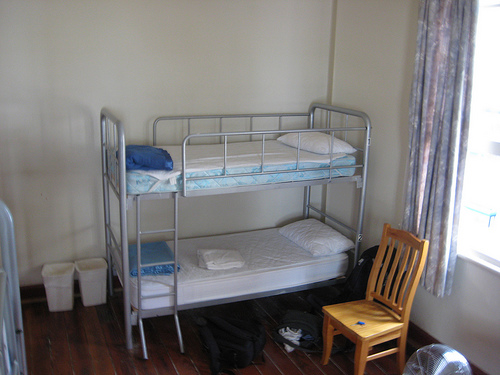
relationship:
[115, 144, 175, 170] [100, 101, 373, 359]
blanket laying on bed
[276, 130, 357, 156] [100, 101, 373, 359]
pillow laying on bed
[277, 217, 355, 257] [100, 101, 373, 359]
pillow laying on bed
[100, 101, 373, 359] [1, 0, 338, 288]
bed against wall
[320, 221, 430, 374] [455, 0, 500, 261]
chair sitting near window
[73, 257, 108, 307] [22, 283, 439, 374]
waste basket sitting on floor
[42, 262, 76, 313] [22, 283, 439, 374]
waste basket sitting on floor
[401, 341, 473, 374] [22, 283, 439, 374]
fan sitting on floor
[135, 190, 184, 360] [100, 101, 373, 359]
ladder on bed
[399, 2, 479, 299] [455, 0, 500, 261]
curtain on window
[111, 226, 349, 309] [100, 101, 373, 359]
mattress on bed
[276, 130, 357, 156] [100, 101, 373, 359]
pillow on bed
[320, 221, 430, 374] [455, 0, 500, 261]
chair in front of window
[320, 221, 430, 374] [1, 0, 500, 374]
chair in room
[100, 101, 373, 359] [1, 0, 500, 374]
bed in room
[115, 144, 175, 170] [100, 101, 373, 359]
blanket on bed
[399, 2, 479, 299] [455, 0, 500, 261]
curtain for window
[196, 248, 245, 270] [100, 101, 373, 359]
sheet for bed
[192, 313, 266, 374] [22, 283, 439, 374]
back pack on floor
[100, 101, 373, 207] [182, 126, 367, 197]
top has guard rail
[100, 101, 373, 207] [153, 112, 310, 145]
top has guard rail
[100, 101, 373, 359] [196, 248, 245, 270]
bed has sheet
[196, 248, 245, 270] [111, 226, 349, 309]
sheet on mattress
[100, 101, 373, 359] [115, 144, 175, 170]
bed has blanket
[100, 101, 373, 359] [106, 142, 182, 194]
bed has foot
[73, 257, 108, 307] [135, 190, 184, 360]
waste basket at ladder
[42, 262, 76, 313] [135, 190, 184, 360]
waste basket at ladder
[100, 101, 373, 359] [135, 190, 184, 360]
bed has ladder